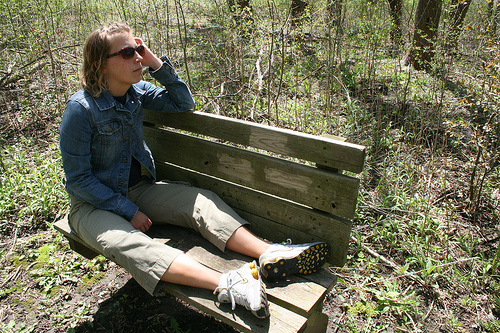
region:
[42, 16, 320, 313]
a person enjoying nature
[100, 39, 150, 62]
a pair of sunglasses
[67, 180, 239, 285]
a pair of tan pants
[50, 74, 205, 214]
a blue jean jacket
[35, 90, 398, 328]
a wooden bench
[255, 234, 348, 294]
a hiker's left shoe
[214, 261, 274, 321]
a hiker's right shoe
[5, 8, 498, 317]
a patch of short brush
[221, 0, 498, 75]
several tree trunks in the background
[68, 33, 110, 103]
curly light brown hair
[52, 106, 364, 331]
the wooden bench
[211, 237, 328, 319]
the white shoes on the woman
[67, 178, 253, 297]
the capri pants on the woman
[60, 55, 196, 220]
the denim jacket on the woman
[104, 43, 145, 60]
the sunglasses on the woman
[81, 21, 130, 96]
the hair on the woman's head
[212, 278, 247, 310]
the shoelaces on the woman's foot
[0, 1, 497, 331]
the dirt on the ground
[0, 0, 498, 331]
the thin branches around the bench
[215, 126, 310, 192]
the lighter areas on the bench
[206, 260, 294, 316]
white shoe on person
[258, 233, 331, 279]
white shoe on person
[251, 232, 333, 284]
left foot on person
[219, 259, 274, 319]
right foot on person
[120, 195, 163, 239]
right hand on person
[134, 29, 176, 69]
left hand on person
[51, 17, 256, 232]
person in jean jacket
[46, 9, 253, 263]
person wearing jean jacket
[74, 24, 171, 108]
person wearing black shades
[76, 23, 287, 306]
person in tan capris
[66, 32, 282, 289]
A woman sitting on the bench.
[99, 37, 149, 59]
The woman is wearing sunglasses.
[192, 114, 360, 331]
The bench is wooden.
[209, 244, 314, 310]
The woman is wearing sneakers.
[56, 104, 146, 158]
The woman is wearing a jean jacket.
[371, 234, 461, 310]
Branches on the ground.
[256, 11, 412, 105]
Bare trees behind the bench.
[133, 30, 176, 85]
The lady is on her ear.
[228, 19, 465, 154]
Bushes behind the bench.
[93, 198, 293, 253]
the pants is tan.